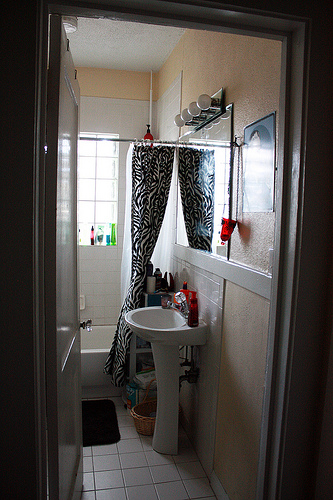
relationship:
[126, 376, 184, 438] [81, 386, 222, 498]
basket on floor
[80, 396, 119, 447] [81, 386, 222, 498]
rug on floor